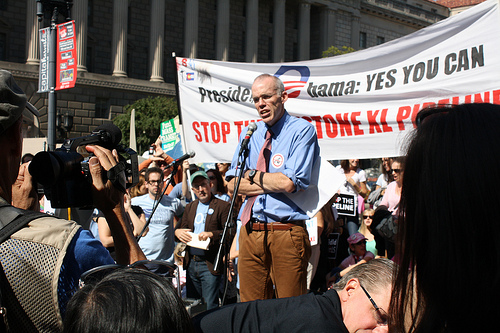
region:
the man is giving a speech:
[179, 70, 335, 300]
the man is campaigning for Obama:
[177, 60, 402, 109]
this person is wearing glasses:
[313, 256, 441, 331]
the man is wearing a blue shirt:
[191, 90, 356, 308]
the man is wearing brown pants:
[216, 72, 321, 267]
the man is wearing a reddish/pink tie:
[241, 129, 293, 234]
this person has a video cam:
[31, 117, 145, 231]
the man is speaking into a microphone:
[117, 117, 330, 229]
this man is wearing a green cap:
[179, 166, 229, 314]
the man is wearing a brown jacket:
[178, 167, 231, 292]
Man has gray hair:
[207, 57, 334, 203]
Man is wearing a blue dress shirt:
[190, 95, 346, 240]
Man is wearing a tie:
[220, 116, 290, 236]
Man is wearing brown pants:
[210, 212, 340, 303]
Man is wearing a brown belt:
[212, 195, 312, 250]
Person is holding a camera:
[3, 70, 153, 255]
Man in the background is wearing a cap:
[167, 163, 232, 269]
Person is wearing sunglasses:
[307, 240, 427, 330]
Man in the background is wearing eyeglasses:
[128, 161, 184, 262]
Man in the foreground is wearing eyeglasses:
[218, 68, 320, 195]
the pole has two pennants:
[22, 19, 149, 109]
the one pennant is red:
[58, 11, 89, 103]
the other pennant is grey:
[26, 18, 58, 115]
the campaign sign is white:
[190, 17, 467, 225]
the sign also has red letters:
[183, 65, 499, 167]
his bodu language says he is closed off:
[226, 53, 338, 303]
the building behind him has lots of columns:
[102, 22, 178, 85]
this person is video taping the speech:
[3, 98, 164, 329]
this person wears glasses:
[304, 246, 426, 328]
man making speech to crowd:
[208, 61, 317, 293]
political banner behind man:
[168, 23, 498, 180]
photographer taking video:
[3, 90, 133, 218]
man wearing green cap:
[169, 163, 229, 270]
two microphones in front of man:
[144, 116, 267, 258]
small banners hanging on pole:
[15, 14, 80, 112]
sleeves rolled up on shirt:
[221, 106, 313, 228]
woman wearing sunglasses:
[386, 160, 406, 187]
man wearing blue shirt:
[123, 160, 188, 270]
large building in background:
[6, 3, 456, 99]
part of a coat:
[272, 303, 307, 323]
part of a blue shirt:
[293, 159, 309, 184]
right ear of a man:
[344, 276, 358, 297]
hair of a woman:
[118, 275, 183, 310]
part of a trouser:
[268, 250, 298, 285]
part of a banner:
[341, 118, 374, 148]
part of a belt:
[263, 223, 280, 235]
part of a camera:
[50, 160, 79, 182]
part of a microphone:
[237, 122, 250, 142]